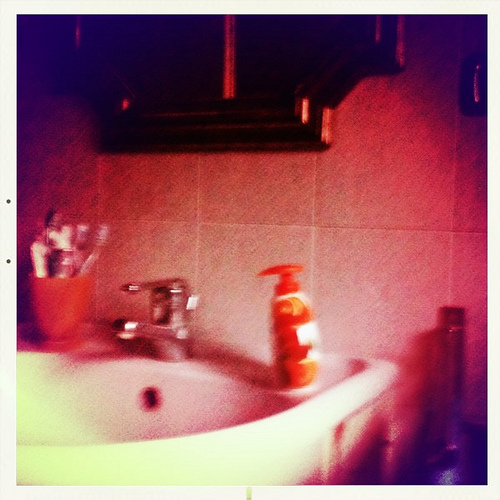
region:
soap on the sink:
[251, 255, 330, 400]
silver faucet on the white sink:
[111, 278, 204, 363]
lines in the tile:
[300, 192, 406, 244]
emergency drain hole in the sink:
[137, 379, 169, 415]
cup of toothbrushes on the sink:
[25, 205, 116, 337]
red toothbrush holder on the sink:
[19, 268, 114, 345]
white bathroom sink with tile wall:
[13, 186, 403, 488]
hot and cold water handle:
[112, 273, 214, 291]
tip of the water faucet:
[112, 320, 142, 342]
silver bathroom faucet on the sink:
[103, 268, 201, 369]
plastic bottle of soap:
[250, 252, 323, 391]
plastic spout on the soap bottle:
[255, 259, 305, 293]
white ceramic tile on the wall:
[309, 230, 456, 365]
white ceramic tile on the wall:
[190, 216, 320, 356]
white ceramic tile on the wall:
[196, 143, 321, 225]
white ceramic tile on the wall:
[312, 45, 462, 235]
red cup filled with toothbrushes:
[20, 205, 112, 342]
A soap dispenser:
[272, 305, 306, 383]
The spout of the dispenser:
[263, 270, 295, 274]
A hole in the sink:
[149, 392, 153, 402]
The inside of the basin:
[29, 416, 97, 439]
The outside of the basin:
[64, 453, 124, 473]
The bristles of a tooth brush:
[98, 227, 103, 244]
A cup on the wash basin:
[38, 284, 78, 325]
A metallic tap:
[126, 326, 181, 337]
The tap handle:
[128, 287, 161, 289]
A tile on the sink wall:
[213, 246, 248, 308]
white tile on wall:
[313, 229, 451, 392]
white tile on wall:
[449, 230, 481, 414]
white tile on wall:
[193, 220, 312, 353]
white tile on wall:
[95, 222, 196, 335]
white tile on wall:
[19, 215, 95, 316]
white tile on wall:
[18, 97, 99, 220]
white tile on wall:
[99, 154, 194, 223]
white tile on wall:
[198, 155, 315, 225]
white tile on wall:
[315, 47, 451, 234]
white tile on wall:
[458, 40, 485, 233]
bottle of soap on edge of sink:
[257, 260, 315, 382]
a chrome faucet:
[110, 275, 192, 362]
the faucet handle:
[123, 273, 184, 293]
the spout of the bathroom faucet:
[114, 317, 138, 341]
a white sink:
[14, 316, 392, 476]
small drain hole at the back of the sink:
[137, 387, 157, 409]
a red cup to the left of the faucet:
[33, 275, 91, 349]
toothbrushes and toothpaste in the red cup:
[32, 210, 106, 275]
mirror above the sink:
[54, 20, 411, 150]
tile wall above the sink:
[25, 20, 489, 353]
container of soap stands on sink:
[254, 257, 323, 392]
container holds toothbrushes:
[26, 206, 112, 353]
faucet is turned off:
[109, 274, 203, 367]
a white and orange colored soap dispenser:
[251, 261, 316, 391]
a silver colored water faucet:
[108, 275, 188, 360]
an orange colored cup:
[26, 270, 93, 350]